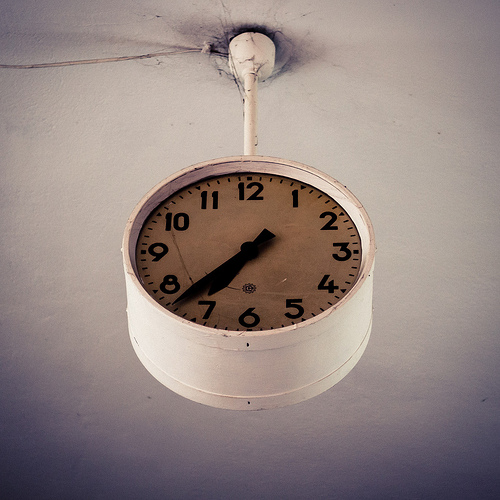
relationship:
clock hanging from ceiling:
[120, 155, 377, 412] [2, 0, 499, 500]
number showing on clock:
[236, 180, 265, 202] [120, 155, 377, 412]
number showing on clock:
[290, 188, 302, 209] [120, 155, 377, 412]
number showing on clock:
[319, 210, 340, 231] [120, 155, 377, 412]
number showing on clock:
[317, 273, 340, 296] [120, 155, 377, 412]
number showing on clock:
[282, 297, 307, 320] [120, 155, 377, 412]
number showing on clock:
[197, 299, 218, 321] [120, 155, 377, 412]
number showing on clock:
[147, 240, 170, 263] [120, 155, 377, 412]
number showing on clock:
[163, 210, 192, 231] [120, 155, 377, 412]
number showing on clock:
[198, 188, 220, 211] [120, 155, 377, 412]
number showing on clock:
[158, 274, 181, 295] [120, 155, 377, 412]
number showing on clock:
[237, 306, 261, 328] [120, 155, 377, 412]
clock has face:
[120, 155, 377, 412] [136, 172, 363, 331]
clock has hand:
[120, 155, 377, 412] [172, 228, 277, 303]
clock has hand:
[120, 155, 377, 412] [208, 240, 252, 295]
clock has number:
[120, 155, 377, 412] [236, 180, 265, 202]